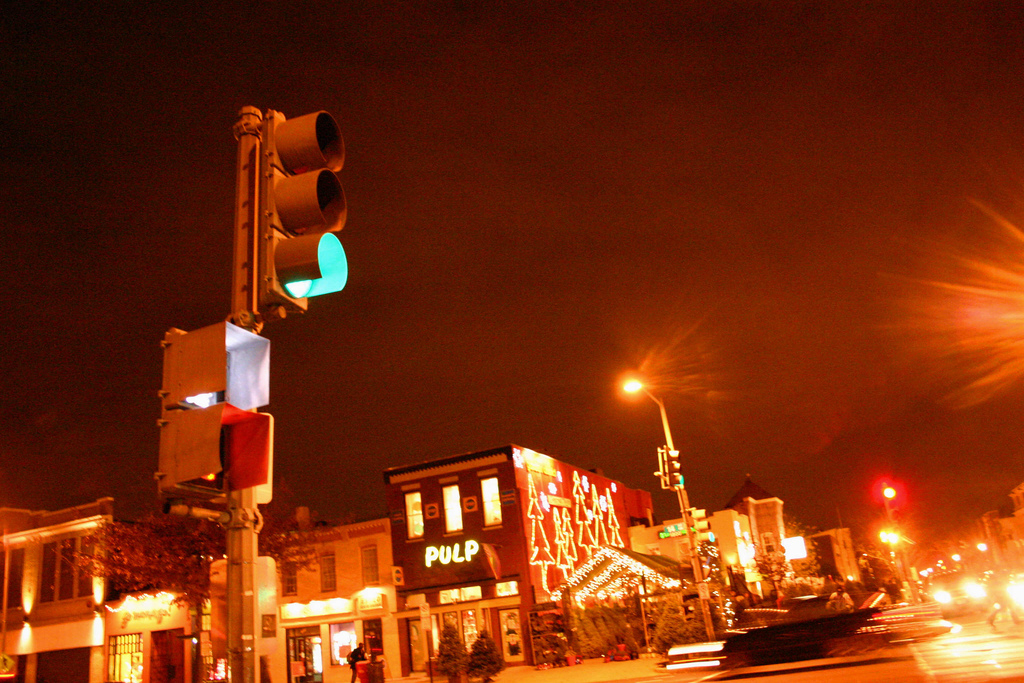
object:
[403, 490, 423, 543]
window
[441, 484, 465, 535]
window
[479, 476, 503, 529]
window